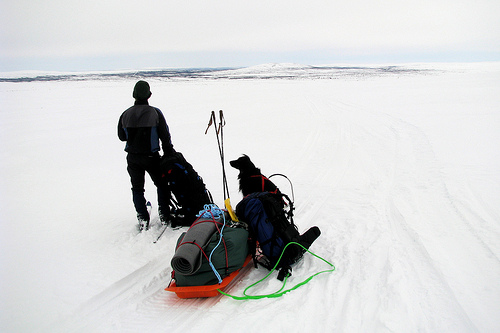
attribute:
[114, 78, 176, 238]
skier — snow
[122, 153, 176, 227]
pants — black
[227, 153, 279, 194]
dog — black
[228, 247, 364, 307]
string — green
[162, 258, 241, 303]
chair — red 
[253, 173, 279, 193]
strap — red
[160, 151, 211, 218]
bag — black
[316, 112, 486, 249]
ground — white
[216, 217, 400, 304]
string — green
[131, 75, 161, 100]
hat — black